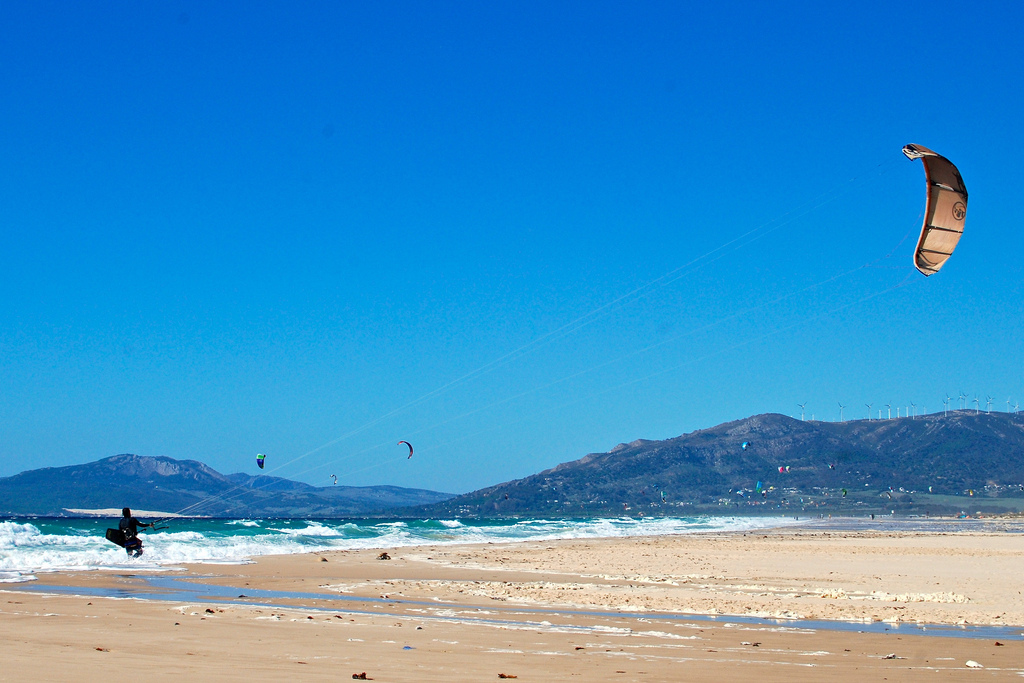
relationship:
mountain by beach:
[133, 446, 281, 513] [0, 500, 988, 676]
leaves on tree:
[252, 480, 320, 541] [401, 418, 544, 535]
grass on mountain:
[671, 414, 885, 520] [440, 309, 966, 603]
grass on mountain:
[671, 414, 885, 520] [544, 296, 940, 575]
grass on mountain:
[671, 414, 885, 520] [497, 329, 984, 619]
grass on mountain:
[671, 346, 860, 519] [579, 355, 906, 580]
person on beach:
[78, 422, 221, 617] [21, 392, 801, 639]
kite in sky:
[898, 134, 974, 273] [153, 104, 748, 351]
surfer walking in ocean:
[101, 498, 141, 555] [6, 515, 194, 565]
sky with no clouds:
[136, 55, 595, 256] [579, 46, 858, 261]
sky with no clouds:
[36, 35, 341, 316] [575, 39, 785, 133]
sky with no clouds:
[67, 135, 292, 235] [445, 42, 884, 265]